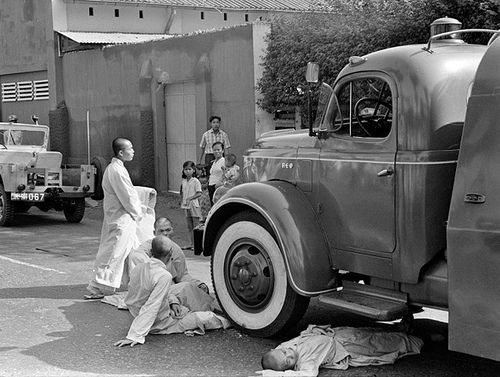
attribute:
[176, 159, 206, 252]
child — looking, standing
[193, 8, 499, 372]
truck — old, parked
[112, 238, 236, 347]
man — sitting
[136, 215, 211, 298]
man — sitting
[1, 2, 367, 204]
building — large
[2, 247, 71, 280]
line — white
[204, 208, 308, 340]
tire — dark colored, black, white, thick, colored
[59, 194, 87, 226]
tire — black, white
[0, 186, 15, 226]
tire — black, white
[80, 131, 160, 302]
man — walking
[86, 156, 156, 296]
robe — white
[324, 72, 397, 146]
window — open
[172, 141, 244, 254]
family — looking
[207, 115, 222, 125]
hair — black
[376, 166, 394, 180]
handle — silver